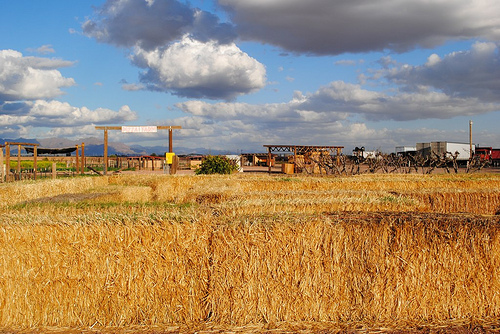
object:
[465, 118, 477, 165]
truck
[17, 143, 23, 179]
pole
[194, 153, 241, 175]
bush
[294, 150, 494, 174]
fence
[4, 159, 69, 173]
grass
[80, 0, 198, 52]
gray cloud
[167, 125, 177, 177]
pole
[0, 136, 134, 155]
mountains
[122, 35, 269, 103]
clouds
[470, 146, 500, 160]
trailer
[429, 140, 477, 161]
ranch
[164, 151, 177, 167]
sign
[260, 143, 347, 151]
top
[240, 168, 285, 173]
shade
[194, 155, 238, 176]
tree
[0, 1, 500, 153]
blue skies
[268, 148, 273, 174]
post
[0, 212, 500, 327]
hay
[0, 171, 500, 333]
ranchland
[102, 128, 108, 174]
pole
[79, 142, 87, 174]
pole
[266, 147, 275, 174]
pole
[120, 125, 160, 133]
sign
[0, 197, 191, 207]
plants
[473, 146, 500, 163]
cab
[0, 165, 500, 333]
field